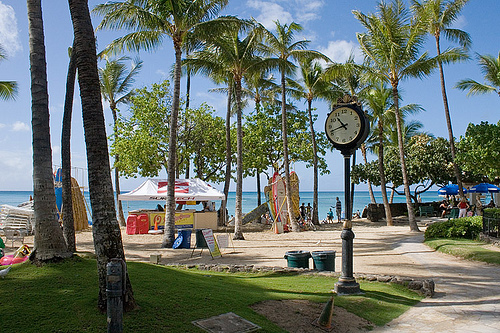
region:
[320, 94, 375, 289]
a clock on a pole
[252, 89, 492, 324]
a clock on a pole in a park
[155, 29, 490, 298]
a clock on a pole amidst palm trees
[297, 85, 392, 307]
a clock on a pole in a park near the beach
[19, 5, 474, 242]
multiple palm trees in a park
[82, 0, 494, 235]
many palm trees in a beach park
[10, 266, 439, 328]
short cut grass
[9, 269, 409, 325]
short cut green grass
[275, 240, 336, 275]
2 green garbage cans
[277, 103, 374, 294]
2 green garbage cans next to a clock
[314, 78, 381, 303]
Clock with a stand on grass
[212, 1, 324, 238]
Palm trees near a beach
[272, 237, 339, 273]
Two trashcans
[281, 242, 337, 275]
Two green trash cans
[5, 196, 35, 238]
A pile of beach furniture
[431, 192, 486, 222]
A group of people some standing and some sitting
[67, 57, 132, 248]
The trunk of a palm tree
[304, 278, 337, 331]
A cone on dirt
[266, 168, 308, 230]
Surfboards learning against a tree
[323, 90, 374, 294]
a clock on a pole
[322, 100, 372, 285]
a pole holding up a clock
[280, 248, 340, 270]
two green trash cans with plastic bags in them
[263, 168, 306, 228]
a group of surfboards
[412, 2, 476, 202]
a tall leaning palm tree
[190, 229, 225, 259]
a sandwich board sign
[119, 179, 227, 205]
a red and white tarp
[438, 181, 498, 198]
two blue umbrellas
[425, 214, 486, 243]
shaped green bushes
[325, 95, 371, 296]
a clock on a pole outside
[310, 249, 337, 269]
a green trashcan with a grey lid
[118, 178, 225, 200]
a red and white canopy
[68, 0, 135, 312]
the trunk of a tall tree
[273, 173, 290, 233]
a red and white surfboard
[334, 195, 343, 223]
a man wearing a striped shirt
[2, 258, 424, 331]
a section of green grass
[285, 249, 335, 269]
two green trash cans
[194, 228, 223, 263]
a folding sign on the sidewalk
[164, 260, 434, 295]
a rock border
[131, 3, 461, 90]
palm trees in the sun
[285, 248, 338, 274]
two green garbage bins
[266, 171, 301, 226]
surfboards near the beach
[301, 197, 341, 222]
people standing on the beach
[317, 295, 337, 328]
construction cone on the dirt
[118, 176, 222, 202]
white canopy over a tent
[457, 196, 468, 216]
woman wearing white pants and a red shirt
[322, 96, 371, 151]
clock that reads 10:42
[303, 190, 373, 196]
ocean water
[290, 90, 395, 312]
A black and gold clock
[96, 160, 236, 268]
a food stand on the beach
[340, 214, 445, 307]
A sand walkway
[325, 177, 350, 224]
Two people between the trees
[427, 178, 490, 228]
A group of people talking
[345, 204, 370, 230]
Two people by the beach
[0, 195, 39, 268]
A stack of beach chairs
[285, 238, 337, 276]
True green trashcan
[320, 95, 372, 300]
Large, circular, outdoor, beach clock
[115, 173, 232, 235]
White, red, and black beach tent.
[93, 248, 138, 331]
Grey and black outdoor water pump.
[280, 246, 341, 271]
Two green trash cans with bags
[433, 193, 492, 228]
People walking to the beach